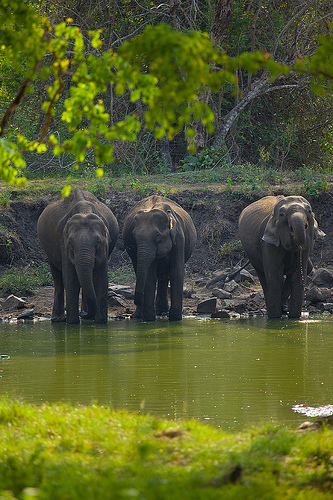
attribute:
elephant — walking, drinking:
[121, 191, 197, 321]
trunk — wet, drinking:
[136, 242, 153, 317]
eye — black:
[155, 231, 165, 239]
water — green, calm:
[3, 315, 332, 431]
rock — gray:
[198, 296, 224, 317]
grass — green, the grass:
[2, 395, 332, 499]